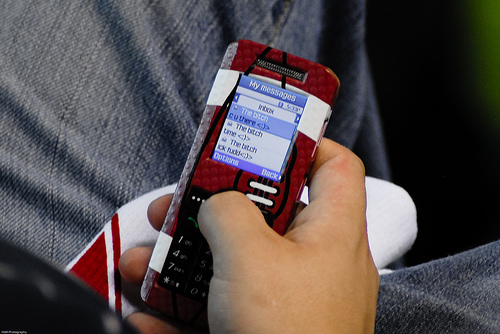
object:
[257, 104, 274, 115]
word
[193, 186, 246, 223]
fingertips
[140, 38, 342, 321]
cell phone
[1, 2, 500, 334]
blue jeans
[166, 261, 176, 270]
numbers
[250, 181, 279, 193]
stripe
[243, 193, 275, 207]
stripe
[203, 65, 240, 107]
white line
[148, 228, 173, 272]
white line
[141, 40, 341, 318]
phone cover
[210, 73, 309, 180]
words/screen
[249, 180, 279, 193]
bar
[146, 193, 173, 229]
finger tip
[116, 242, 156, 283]
finger tip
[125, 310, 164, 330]
finger tip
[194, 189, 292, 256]
thumb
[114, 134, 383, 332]
hand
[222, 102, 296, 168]
messages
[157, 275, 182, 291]
keypad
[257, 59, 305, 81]
speaker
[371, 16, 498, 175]
space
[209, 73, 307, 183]
panel